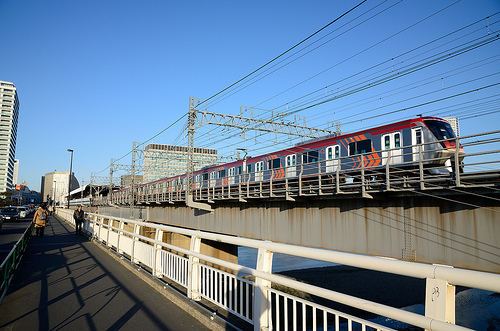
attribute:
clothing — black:
[70, 207, 90, 227]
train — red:
[112, 117, 465, 202]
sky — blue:
[1, 0, 497, 179]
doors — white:
[382, 132, 402, 164]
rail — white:
[49, 204, 499, 330]